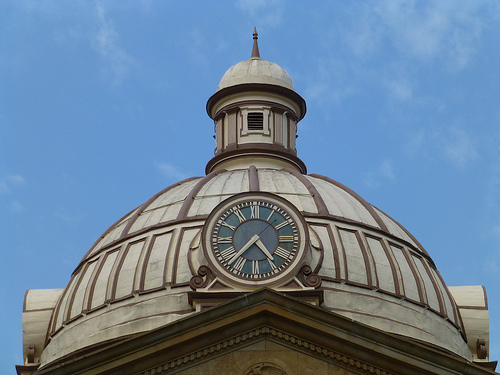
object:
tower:
[15, 26, 499, 375]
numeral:
[277, 234, 294, 243]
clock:
[200, 190, 311, 288]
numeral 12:
[248, 205, 261, 219]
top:
[247, 26, 263, 61]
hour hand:
[253, 238, 274, 261]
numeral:
[266, 209, 276, 221]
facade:
[32, 285, 499, 374]